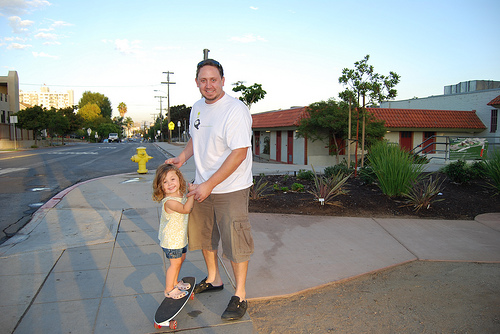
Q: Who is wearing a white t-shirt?
A: The tall male.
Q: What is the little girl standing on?
A: A skateboard.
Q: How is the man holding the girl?
A: From the hands.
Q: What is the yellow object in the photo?
A: A fire hydrant.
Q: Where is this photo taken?
A: In a neighborhood.